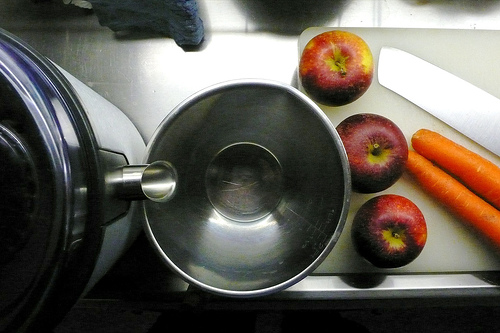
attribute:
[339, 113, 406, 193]
apple — red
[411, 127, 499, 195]
carrot — orange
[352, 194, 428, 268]
apple — red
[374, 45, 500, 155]
knife — silver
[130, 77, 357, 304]
bowl — silver, deep, empty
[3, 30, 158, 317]
juicer — plastic, used, electric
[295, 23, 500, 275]
board — white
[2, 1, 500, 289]
counter — large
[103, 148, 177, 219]
nozzle — silver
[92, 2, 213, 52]
cloth — blue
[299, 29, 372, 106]
apple — red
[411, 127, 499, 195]
carotte — orange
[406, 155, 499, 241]
carotte — orange